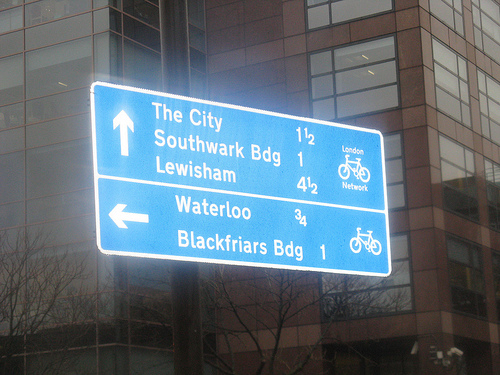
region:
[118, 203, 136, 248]
white arrow pointing west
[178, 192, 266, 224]
white letters on green sign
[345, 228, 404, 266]
symbol of bike on sign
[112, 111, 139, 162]
white arrow pointing north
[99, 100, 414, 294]
light reflecting off sign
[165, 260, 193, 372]
black pole green and white sign is on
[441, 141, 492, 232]
black windows in brown building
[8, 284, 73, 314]
reflection of bare trees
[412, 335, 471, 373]
white lights on brown building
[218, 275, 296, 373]
black bare tree on corner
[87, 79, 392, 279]
large blue and white directions street sign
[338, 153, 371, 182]
white bicycle icon on large street sign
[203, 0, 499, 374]
large brown building in background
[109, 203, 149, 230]
large white left arrow on blue sign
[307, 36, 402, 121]
large glass window with brown frame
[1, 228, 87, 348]
reflection of tree on glass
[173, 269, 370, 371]
bare tree in front of building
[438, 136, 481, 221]
window on tall building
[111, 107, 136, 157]
forward arrow on blue sign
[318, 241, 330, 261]
number one on blue sign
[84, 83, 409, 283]
this is a sign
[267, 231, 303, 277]
a word on the sign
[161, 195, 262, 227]
a word on the sign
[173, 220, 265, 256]
a word on the sign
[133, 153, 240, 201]
a word on the sign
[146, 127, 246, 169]
a word on the sign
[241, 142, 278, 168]
a word on the sign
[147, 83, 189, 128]
a word on the sign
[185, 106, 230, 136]
a word on the sign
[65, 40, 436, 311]
the sign is blue and white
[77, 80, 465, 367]
the sign is blue with white writing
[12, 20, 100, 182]
the building has several windowsf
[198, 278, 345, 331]
the branches have no leaves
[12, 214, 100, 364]
the trees are reflecting in the window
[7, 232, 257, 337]
the trees are in front of the building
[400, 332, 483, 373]
the cameras are on the building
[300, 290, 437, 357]
the windows are outlined in black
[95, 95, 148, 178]
the arrow is pointing up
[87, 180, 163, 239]
the arrow is pointing to the left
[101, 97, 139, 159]
white arrow pointing up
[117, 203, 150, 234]
white arrow pointing left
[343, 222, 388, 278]
bike symbol on the sign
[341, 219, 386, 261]
bike symbol is in white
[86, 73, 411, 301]
street sign is green and white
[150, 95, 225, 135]
The City is on the sign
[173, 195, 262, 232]
Waterloo is on the sign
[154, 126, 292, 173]
Southwark Bdg is on the sign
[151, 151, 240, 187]
Lewisham is written in white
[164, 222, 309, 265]
Blackfriears Bdg is on sign